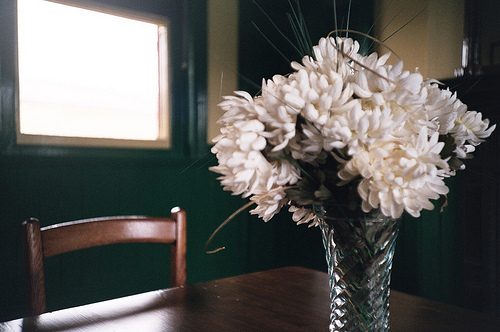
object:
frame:
[12, 0, 171, 146]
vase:
[310, 203, 397, 330]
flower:
[210, 38, 494, 231]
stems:
[290, 158, 362, 217]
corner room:
[238, 1, 378, 99]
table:
[0, 263, 499, 329]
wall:
[4, 171, 216, 320]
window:
[13, 0, 169, 147]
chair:
[22, 204, 190, 311]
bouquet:
[216, 35, 499, 217]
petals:
[404, 187, 419, 216]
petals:
[410, 157, 427, 172]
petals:
[373, 173, 384, 209]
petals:
[328, 105, 368, 125]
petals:
[370, 112, 405, 129]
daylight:
[18, 15, 163, 139]